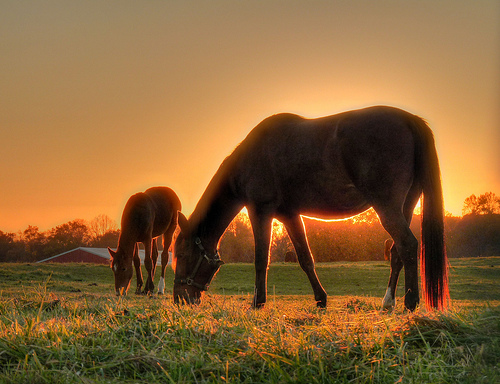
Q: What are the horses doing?
A: Eating.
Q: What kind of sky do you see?
A: Clear.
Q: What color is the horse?
A: Brown.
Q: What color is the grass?
A: Green.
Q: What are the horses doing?
A: Eating.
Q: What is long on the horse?
A: Tail.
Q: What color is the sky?
A: Orange.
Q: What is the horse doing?
A: Eating.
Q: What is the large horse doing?
A: Eating grass.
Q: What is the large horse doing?
A: Eating grass.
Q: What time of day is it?
A: Sunset.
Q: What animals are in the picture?
A: Horses.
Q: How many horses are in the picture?
A: 2.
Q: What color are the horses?
A: Brown.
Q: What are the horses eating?
A: Grass.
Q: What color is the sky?
A: Orange.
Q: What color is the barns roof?
A: White.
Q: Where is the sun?
A: Behind the horses.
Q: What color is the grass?
A: Green.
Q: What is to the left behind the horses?
A: The barn.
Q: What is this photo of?
A: Two horses.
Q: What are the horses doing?
A: Eating grass.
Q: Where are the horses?
A: On a grass prairie.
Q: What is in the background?
A: Trees.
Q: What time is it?
A: Sunset.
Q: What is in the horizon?
A: The sun setting.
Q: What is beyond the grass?
A: A barn.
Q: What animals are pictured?
A: Horses.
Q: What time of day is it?
A: Sunset.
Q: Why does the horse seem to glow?
A: Setting sun.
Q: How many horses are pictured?
A: 2.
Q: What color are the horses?
A: Brown.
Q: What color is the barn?
A: Red.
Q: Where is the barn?
A: Left.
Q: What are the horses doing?
A: Grazing.